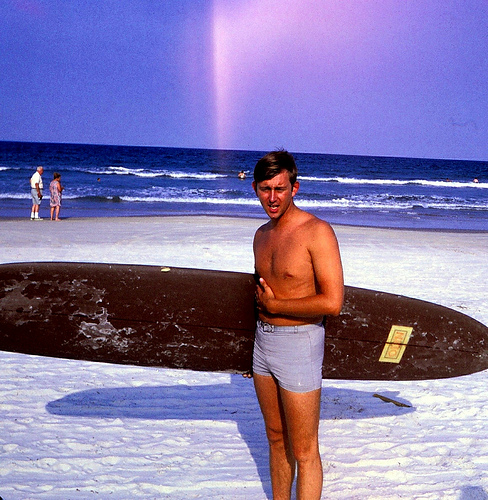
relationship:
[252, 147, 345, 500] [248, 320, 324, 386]
man wearing shorts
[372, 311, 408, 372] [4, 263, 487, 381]
sticker on board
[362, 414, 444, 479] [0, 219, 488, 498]
footprints are on sand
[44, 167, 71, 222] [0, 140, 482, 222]
woman by water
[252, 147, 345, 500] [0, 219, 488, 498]
man standing in sand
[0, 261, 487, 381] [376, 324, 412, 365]
surfboard has sticker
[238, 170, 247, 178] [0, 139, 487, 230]
person in water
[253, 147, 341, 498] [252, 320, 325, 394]
man wearing shorts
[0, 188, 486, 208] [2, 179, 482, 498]
wave breaking on beach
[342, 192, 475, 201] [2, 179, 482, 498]
wave breaking on beach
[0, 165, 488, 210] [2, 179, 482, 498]
wave breaking on beach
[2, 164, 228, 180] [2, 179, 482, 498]
wave breaking on beach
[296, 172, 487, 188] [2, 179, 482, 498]
wave breaking on beach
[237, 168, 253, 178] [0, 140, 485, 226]
person in ocean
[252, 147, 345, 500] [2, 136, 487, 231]
man in ocean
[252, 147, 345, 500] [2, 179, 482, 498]
man on beach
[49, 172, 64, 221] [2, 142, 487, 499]
woman standing on beach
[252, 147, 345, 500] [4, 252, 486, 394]
man holding surfboard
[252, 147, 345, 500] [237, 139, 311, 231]
man has head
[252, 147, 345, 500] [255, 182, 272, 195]
man has eye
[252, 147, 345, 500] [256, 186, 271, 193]
man has eye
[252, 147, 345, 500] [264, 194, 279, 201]
man has nose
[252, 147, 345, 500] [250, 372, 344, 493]
man has legs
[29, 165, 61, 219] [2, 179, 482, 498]
couple standing on beach